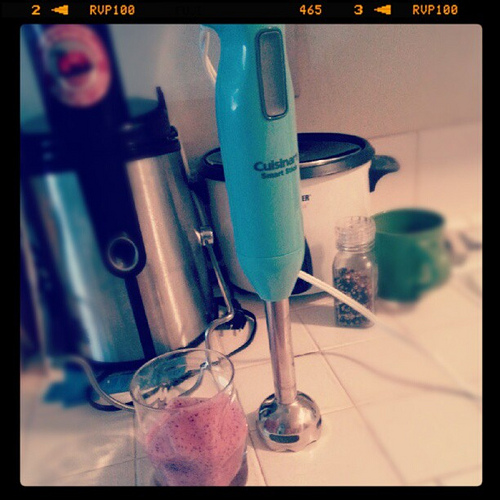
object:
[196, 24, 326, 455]
immerision blender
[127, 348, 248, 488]
smoothie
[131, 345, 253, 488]
glass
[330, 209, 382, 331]
pepper grinder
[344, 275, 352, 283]
peppercorn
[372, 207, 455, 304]
mug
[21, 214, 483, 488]
kitchen counter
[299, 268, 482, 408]
electrical cord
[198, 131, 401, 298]
appliance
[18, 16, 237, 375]
appliance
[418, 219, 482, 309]
sink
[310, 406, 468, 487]
ceramic tile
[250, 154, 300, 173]
company logo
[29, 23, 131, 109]
design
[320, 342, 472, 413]
ceramic tile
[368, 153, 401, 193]
handle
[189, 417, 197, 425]
seed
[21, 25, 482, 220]
wall